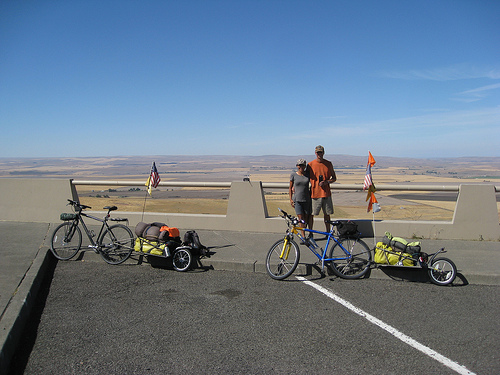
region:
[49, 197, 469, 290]
Row of bicycles with back seats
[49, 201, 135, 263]
Black bicycle with a back seat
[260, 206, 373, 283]
Blue bicycle with a back seat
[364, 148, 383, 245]
Set of colored flags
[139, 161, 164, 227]
American flag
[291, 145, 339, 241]
Owners of the bicycles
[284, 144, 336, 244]
Couple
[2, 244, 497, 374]
Gray parking lot with white segments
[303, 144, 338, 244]
Male with an orange shirt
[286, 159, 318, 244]
Female with a gray shirt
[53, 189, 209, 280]
bike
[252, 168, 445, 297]
bike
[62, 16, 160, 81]
white clouds in blue sky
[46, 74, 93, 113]
white clouds in blue sky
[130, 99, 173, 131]
white clouds in blue sky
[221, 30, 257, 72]
white clouds in blue sky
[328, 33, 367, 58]
white clouds in blue sky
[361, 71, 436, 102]
white clouds in blue sky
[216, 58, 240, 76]
white clouds in blue sky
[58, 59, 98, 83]
white clouds in blue sky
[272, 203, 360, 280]
bike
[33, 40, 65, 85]
blue sky with no clouds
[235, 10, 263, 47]
blue sky with no clouds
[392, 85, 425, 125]
blue sky with no clouds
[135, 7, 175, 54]
blue sky with no clouds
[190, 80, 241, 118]
blue sky with no clouds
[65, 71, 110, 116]
blue sky with no clouds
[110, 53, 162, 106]
blue sky with no clouds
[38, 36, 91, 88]
blue sky with no clouds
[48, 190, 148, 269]
the bike is black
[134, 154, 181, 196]
a flag of USA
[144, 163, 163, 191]
flag hanging from stick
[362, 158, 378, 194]
american flag hanging on stick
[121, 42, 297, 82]
clear blue sky in air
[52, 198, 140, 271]
black mountain bike in lot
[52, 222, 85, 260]
black front tire on bike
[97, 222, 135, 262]
black back tire on bike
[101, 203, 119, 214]
black seat on the bike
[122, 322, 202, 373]
black cement pavement on ground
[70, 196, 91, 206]
handle bars on black bike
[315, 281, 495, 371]
white line painted in road